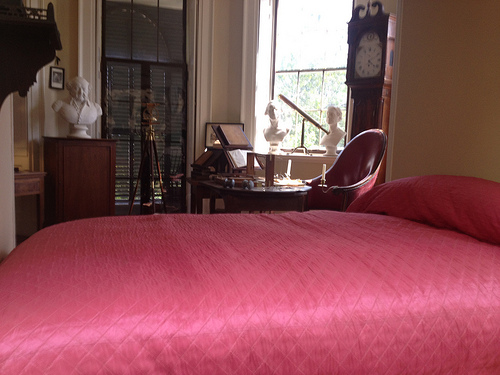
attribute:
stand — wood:
[36, 113, 131, 237]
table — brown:
[188, 162, 313, 209]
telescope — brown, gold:
[134, 95, 169, 202]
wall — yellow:
[403, 29, 480, 143]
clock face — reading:
[348, 33, 398, 92]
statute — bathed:
[262, 98, 288, 145]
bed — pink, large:
[1, 175, 498, 374]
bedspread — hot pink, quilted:
[17, 197, 497, 367]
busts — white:
[257, 93, 352, 160]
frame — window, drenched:
[238, 1, 357, 163]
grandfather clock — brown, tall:
[343, 0, 398, 187]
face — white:
[353, 44, 381, 78]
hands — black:
[365, 59, 378, 70]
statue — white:
[55, 74, 100, 140]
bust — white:
[316, 103, 346, 155]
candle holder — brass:
[315, 177, 328, 187]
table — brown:
[182, 174, 326, 211]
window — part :
[270, 7, 353, 154]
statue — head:
[316, 98, 343, 158]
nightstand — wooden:
[15, 171, 49, 237]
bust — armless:
[57, 79, 102, 135]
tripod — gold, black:
[124, 107, 170, 207]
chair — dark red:
[303, 127, 386, 211]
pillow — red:
[344, 165, 496, 243]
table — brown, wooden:
[200, 171, 323, 217]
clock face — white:
[351, 28, 383, 77]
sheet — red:
[6, 203, 485, 367]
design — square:
[52, 220, 239, 310]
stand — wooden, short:
[12, 165, 46, 245]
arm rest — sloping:
[322, 172, 373, 211]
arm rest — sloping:
[297, 164, 333, 204]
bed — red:
[6, 151, 484, 361]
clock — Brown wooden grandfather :
[342, 0, 384, 145]